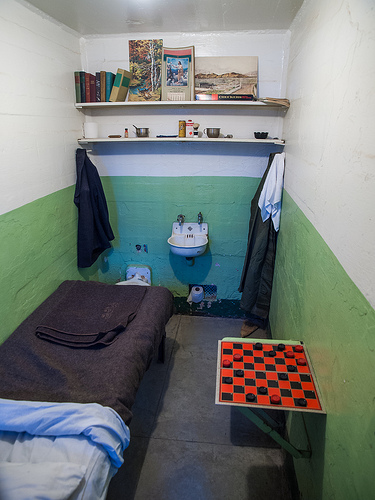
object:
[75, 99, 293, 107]
shelf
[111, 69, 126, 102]
book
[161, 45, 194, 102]
calendar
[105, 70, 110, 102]
book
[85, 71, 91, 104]
book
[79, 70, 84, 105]
book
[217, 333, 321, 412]
board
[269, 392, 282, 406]
checker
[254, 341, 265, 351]
checker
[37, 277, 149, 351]
blanket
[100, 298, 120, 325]
printing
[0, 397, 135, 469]
sheet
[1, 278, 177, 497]
bed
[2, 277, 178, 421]
blanket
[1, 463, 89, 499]
pillow case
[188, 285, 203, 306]
paper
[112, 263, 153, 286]
toilet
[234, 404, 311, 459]
support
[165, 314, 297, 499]
floor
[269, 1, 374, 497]
wall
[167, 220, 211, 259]
sink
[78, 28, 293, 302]
wall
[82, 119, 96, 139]
paper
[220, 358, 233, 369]
checker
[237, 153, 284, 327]
coat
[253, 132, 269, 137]
ashtray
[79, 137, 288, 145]
shelf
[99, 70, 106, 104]
book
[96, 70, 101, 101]
book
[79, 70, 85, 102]
book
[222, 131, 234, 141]
brush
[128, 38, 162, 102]
picture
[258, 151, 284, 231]
towel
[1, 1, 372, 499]
room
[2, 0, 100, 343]
wall